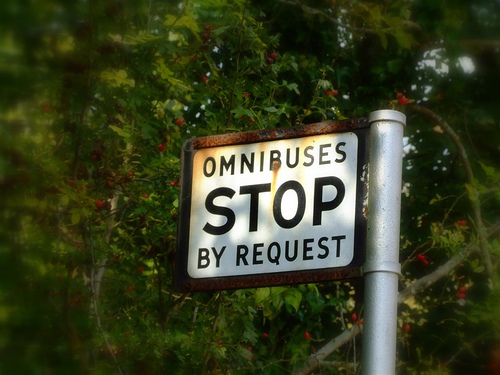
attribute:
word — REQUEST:
[235, 233, 345, 266]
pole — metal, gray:
[358, 99, 406, 374]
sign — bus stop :
[135, 124, 369, 309]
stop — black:
[205, 175, 348, 237]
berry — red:
[301, 331, 311, 343]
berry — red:
[414, 251, 429, 266]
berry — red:
[172, 116, 186, 129]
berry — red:
[197, 74, 207, 82]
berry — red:
[200, 22, 210, 34]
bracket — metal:
[363, 257, 403, 277]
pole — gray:
[359, 106, 406, 358]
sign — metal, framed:
[174, 118, 399, 282]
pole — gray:
[155, 101, 390, 307]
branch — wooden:
[305, 220, 497, 366]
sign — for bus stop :
[169, 113, 370, 296]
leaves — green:
[86, 29, 320, 112]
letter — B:
[195, 246, 211, 267]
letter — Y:
[208, 243, 227, 267]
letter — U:
[282, 237, 301, 262]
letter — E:
[300, 236, 315, 262]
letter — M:
[216, 152, 238, 177]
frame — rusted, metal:
[177, 119, 367, 294]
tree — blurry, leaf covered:
[3, 0, 139, 372]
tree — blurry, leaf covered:
[145, 73, 354, 369]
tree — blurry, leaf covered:
[258, 0, 448, 367]